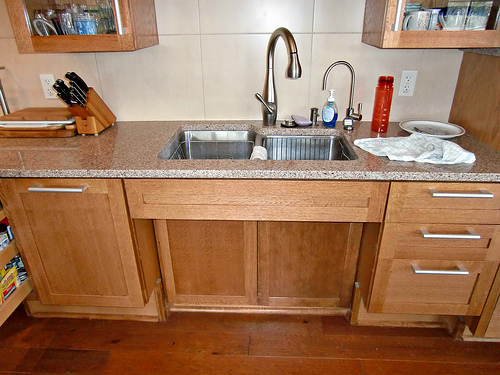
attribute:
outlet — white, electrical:
[400, 69, 415, 96]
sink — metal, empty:
[256, 131, 356, 164]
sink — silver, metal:
[158, 129, 356, 162]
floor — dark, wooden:
[0, 304, 500, 374]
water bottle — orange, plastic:
[368, 73, 397, 135]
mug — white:
[392, 5, 428, 39]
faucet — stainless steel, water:
[254, 27, 301, 127]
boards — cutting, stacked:
[0, 107, 80, 141]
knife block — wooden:
[52, 71, 127, 143]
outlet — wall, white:
[31, 71, 58, 106]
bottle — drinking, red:
[368, 75, 394, 132]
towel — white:
[357, 124, 484, 172]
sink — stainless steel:
[161, 123, 256, 158]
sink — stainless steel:
[261, 130, 354, 160]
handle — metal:
[428, 189, 491, 199]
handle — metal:
[420, 229, 481, 240]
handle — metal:
[411, 263, 470, 275]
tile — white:
[161, 26, 243, 86]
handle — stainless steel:
[430, 186, 495, 201]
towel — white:
[346, 117, 474, 165]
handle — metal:
[26, 180, 88, 194]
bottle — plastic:
[320, 87, 338, 127]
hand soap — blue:
[318, 110, 338, 123]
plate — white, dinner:
[398, 114, 465, 141]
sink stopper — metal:
[276, 115, 301, 130]